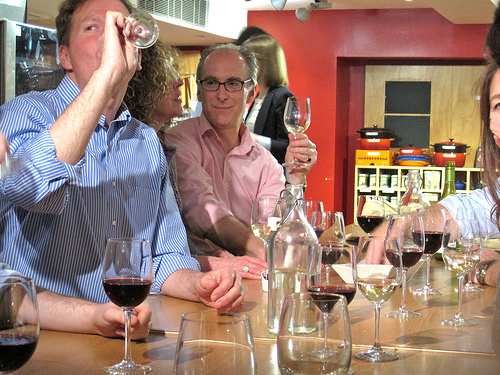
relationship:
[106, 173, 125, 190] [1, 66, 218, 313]
button on shirt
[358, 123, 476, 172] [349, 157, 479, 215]
cooking utensils on shelf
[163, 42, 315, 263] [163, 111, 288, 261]
man in shirt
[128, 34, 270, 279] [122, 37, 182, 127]
woman with hair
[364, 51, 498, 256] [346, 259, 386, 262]
woman reaching food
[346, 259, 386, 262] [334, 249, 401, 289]
food on dish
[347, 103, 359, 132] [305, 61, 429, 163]
edge of wall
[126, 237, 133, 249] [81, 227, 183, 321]
edge of cup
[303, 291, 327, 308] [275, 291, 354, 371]
glass edge of glass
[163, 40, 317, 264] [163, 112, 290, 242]
man wearing shirt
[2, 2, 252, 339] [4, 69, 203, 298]
man wearing shirt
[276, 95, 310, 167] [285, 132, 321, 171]
glass on finger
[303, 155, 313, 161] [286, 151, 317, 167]
ring on finger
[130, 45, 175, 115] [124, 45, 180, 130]
curly hair of curly hair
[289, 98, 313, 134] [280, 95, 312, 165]
shine reflection on a glass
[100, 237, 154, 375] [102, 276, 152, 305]
cup filled with red wine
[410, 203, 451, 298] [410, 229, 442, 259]
glass filled with red wine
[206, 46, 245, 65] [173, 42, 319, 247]
bald head of a man